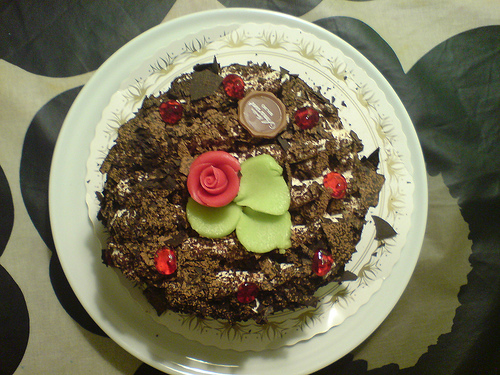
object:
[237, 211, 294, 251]
leaves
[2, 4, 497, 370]
table cloth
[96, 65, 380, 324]
icing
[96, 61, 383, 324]
cake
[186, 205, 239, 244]
leaves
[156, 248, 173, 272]
jelly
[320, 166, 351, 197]
candied cherry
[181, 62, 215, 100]
chocolate shaving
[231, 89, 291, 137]
brown disc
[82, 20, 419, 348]
doily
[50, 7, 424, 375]
dessert plate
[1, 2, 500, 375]
table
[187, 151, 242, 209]
candy flower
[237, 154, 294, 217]
candy petal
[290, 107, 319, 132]
chocolate chip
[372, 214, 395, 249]
chocolate flake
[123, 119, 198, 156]
brownie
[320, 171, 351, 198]
red flower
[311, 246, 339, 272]
red flower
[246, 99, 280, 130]
writing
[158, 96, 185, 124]
candy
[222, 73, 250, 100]
candy